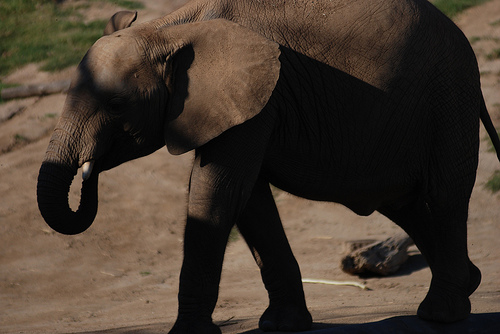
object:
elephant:
[36, 1, 499, 334]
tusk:
[81, 159, 91, 180]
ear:
[163, 17, 281, 156]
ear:
[99, 10, 138, 38]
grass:
[0, 0, 147, 82]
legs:
[174, 142, 261, 321]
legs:
[376, 209, 480, 316]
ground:
[1, 2, 499, 334]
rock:
[337, 235, 415, 278]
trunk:
[37, 130, 102, 237]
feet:
[167, 315, 228, 334]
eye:
[109, 102, 136, 118]